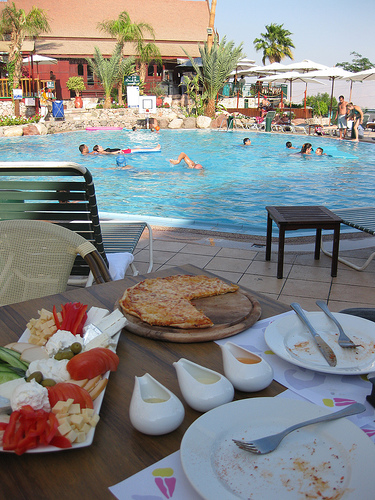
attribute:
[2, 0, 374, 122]
resort — tropical